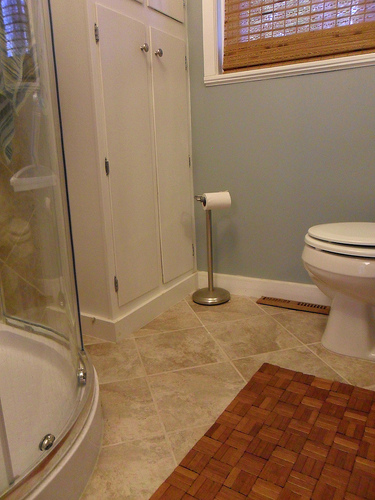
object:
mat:
[147, 362, 375, 500]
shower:
[0, 0, 101, 500]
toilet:
[301, 221, 373, 360]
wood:
[150, 362, 375, 500]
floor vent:
[256, 295, 331, 315]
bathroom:
[1, 1, 374, 499]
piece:
[146, 361, 375, 500]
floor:
[76, 291, 374, 498]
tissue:
[202, 190, 231, 211]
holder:
[193, 191, 232, 306]